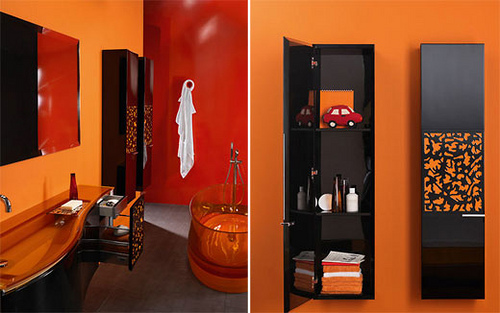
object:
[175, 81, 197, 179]
towel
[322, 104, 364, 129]
toy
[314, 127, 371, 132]
shelf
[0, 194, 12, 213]
faucet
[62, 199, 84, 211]
soap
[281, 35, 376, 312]
cabinet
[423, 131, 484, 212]
pattern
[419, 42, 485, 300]
cabinet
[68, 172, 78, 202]
bottle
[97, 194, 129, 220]
drawer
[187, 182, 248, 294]
tub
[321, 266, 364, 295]
washcloths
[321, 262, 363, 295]
stack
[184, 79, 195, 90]
ring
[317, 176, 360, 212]
toiletries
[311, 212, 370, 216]
shelf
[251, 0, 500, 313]
wall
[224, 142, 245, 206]
faucet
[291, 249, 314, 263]
papers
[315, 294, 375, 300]
shelf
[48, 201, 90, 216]
dish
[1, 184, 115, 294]
counter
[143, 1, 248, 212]
wall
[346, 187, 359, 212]
bottle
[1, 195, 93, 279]
sink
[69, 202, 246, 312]
floor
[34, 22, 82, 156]
mirror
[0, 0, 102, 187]
wall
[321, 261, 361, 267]
book